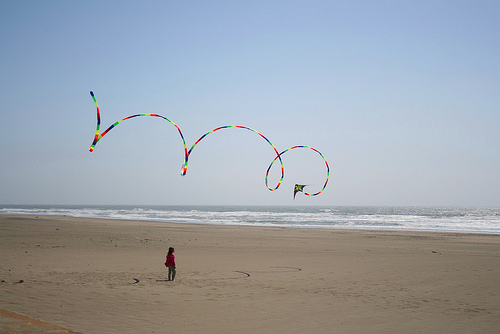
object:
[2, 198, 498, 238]
water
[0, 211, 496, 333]
beach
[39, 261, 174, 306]
shadow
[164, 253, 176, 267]
shirt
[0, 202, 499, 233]
waves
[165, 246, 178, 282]
woman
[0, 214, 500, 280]
shore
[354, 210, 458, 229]
ocean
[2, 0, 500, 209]
sky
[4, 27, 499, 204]
cloud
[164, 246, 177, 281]
person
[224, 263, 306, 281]
reflection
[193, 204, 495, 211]
waters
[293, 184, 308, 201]
kite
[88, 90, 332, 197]
long tail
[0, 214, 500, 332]
sand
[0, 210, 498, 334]
ground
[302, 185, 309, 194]
edge